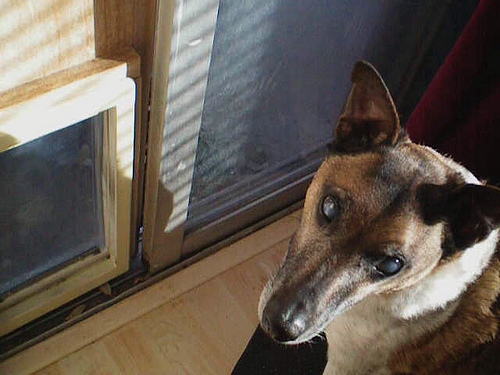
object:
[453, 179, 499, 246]
ear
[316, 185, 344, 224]
eye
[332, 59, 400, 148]
ear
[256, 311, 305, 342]
nose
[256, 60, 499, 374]
dog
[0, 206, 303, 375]
floor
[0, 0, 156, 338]
board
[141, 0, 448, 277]
door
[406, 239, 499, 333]
fur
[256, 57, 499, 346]
head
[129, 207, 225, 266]
sheep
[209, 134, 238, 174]
grass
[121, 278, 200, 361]
sheep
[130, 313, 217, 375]
sheep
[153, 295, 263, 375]
wood